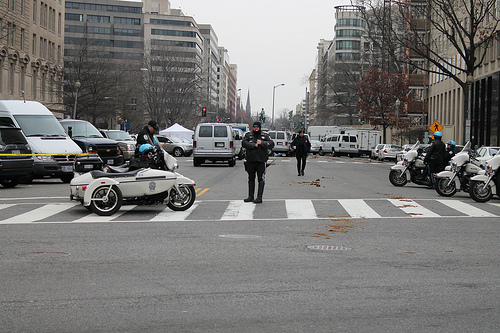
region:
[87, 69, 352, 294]
This is a street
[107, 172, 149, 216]
This is a motorcycle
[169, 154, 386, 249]
This is a crosswalk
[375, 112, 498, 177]
This is a sign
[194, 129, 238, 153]
These are windows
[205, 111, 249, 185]
The car is white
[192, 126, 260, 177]
This is a van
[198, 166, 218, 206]
The lines are yellow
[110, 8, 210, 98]
These are lots of buildings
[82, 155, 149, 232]
This is a wheel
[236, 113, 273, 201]
Police officer standing in the street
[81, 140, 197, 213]
Police Tricycle in the street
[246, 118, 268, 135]
Police officer with hat on his head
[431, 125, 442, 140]
Police officer wearing a blue helmet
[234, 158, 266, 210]
Police officer wearing black boats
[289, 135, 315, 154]
police officer wearing a black jacket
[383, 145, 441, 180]
Motorcycle for a police officer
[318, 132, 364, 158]
White van on the road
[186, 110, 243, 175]
Van parked on the street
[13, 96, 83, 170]
Van in a parking lot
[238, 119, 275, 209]
the manis standing in the streeet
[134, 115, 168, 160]
the man is standing by the motorcycle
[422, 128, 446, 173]
the person is sitting on the motorcycle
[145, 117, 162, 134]
the hat is black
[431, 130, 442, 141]
the helmet is blue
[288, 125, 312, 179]
the man is walking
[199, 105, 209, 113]
the light is red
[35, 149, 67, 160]
the caution tape is yellow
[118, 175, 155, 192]
the motorcycle is white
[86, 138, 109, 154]
the car is black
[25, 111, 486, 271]
The people are all police officers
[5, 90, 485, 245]
The people work for the police department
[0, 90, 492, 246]
The people are law enforcement personnel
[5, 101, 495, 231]
The policemen are going on patrol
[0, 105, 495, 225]
The policemen are beginning their day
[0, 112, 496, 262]
The policemen are at the station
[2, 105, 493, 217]
The policemen are in a parking lot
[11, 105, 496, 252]
The policemen are wearing their uniform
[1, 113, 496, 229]
The policemen have finished their shift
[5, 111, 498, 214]
The policemen are armed with guns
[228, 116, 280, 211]
The man is standing.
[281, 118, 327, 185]
The man is standing.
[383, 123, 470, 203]
The man is on a motorcycle.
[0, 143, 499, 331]
White lines are painted on the street.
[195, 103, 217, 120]
The streetlight is red.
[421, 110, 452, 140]
A walking figure is on the sign.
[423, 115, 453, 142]
The walking figure is black.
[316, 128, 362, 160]
The vehicle is white.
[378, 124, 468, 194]
The motorcycle is white.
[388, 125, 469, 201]
The man is wearing a helmet.